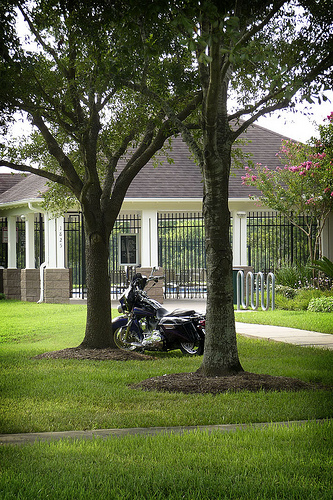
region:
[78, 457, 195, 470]
green grass on the ground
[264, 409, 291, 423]
loose blade of green grass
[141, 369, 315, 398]
large mound of dirt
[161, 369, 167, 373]
white paper on dirt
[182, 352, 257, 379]
dirt at bottom of tree trunk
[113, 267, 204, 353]
large bike parked under tree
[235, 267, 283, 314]
large silver railing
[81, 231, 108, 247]
small cross etched in tree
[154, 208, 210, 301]
iron bars around building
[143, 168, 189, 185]
gray shingles on top of roof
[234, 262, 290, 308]
rack for bikes to stand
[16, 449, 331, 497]
grass on the field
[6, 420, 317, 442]
concrete between grass sections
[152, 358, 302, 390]
mulch under the tree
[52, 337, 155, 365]
mulch under the tree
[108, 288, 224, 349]
bike with motor on it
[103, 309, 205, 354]
tires on the bike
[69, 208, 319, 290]
fence to the building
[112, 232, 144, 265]
plaque on the fence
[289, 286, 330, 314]
plants on the ground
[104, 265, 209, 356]
Motorcycle parked on grass.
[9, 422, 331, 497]
Green grass on ground.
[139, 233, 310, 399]
Tree trunk surrounded by dirt.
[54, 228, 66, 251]
Numbers on white beam.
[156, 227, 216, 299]
Black metal fence.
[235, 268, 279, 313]
Grey squiggly metal bars.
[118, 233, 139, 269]
Black directory with white writing.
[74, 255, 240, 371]
Motorcycle parked between two trees.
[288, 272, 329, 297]
Light colored flowers.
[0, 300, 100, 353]
Sun shining on green grass.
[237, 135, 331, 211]
Pink flowers on a tree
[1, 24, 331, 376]
A motorcycle between two trees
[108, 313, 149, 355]
The motorcycle tire is round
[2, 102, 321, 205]
The roof of a building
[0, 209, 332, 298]
A black iron fence in front of a building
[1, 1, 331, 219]
Green leaves on two trees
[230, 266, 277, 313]
A silver bicycle rack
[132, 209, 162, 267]
A white column of a building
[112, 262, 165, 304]
Handlebars of a motorbike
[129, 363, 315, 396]
Dirt surrounding a tree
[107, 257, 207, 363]
A motorcycle in the center of the image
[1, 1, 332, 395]
Motorcycle is between two trees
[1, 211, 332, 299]
A fence in the background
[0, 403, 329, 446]
A sidewalk in the foreground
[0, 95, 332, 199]
Top of the roof is gray in color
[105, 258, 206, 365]
A side view of a motorcycle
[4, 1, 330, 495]
Photo was taken in the daytime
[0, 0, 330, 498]
Photo was taken outdoors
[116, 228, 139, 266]
A black sign in the background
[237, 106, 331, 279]
Pink flowers are growing on the tree